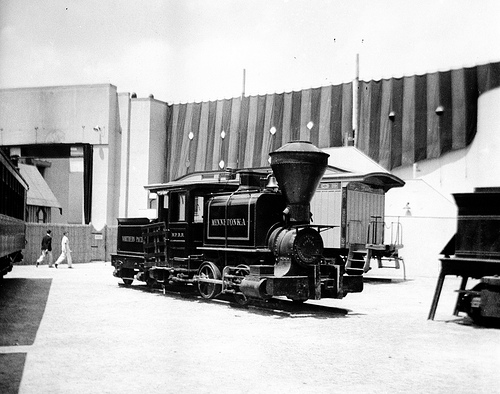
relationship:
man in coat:
[36, 226, 56, 265] [42, 235, 49, 245]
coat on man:
[42, 235, 49, 245] [36, 226, 56, 265]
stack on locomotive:
[265, 113, 320, 220] [109, 139, 406, 312]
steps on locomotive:
[345, 248, 379, 278] [109, 139, 406, 312]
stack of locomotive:
[265, 113, 320, 220] [109, 139, 406, 312]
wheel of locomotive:
[186, 250, 226, 301] [109, 139, 406, 312]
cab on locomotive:
[138, 190, 277, 253] [109, 139, 406, 312]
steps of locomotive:
[345, 248, 379, 278] [109, 139, 406, 312]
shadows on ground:
[312, 302, 341, 317] [125, 348, 180, 368]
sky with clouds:
[32, 23, 108, 52] [307, 10, 349, 22]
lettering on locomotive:
[202, 217, 239, 232] [109, 139, 406, 312]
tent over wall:
[26, 173, 62, 208] [56, 184, 73, 202]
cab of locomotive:
[138, 190, 277, 253] [109, 139, 406, 312]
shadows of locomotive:
[312, 302, 341, 317] [109, 139, 406, 312]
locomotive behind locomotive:
[109, 139, 406, 312] [87, 123, 407, 390]